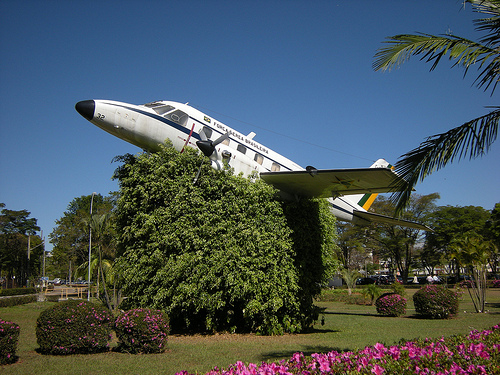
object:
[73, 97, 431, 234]
plane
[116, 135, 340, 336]
tree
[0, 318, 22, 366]
flowers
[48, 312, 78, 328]
flowers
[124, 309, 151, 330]
flowers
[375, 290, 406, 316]
flowers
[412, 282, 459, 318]
flowers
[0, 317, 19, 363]
bush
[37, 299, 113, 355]
bush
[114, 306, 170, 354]
bush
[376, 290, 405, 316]
bush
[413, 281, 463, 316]
bush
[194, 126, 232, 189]
propeller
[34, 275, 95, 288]
vehicles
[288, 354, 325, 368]
flowers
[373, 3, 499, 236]
leaves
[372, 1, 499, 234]
palm tree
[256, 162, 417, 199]
wing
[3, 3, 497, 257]
sky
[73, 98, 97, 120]
nose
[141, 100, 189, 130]
cockpit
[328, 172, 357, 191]
star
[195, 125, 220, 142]
windows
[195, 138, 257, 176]
engine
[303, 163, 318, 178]
light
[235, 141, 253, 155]
windows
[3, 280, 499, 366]
lawn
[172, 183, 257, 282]
leaves